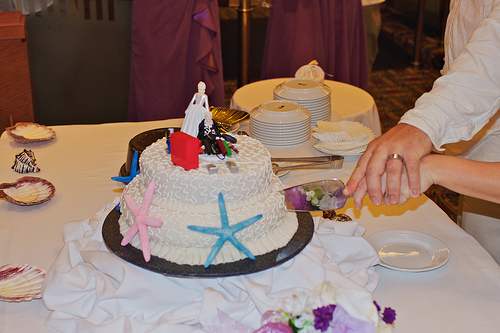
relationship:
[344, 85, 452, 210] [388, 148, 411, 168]
man has ring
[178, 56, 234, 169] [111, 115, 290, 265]
top of cake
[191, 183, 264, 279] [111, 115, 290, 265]
starfish on cake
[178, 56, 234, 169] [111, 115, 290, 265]
figurine on cake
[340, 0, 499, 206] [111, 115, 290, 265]
man cutting cake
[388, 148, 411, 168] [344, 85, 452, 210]
ring on hand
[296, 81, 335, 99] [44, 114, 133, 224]
plate on table